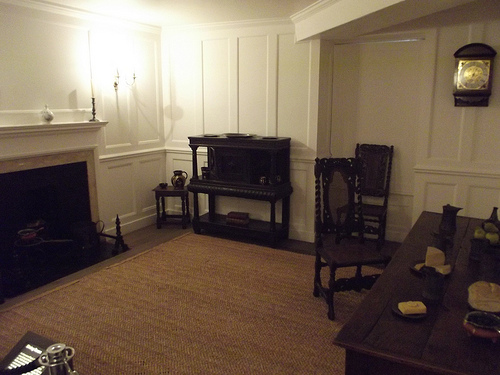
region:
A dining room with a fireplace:
[21, 92, 446, 312]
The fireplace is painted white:
[4, 94, 136, 277]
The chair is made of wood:
[293, 139, 398, 319]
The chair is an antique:
[306, 148, 382, 298]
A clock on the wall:
[442, 26, 493, 111]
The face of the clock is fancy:
[455, 54, 492, 94]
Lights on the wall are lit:
[98, 57, 143, 103]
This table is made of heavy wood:
[334, 284, 481, 369]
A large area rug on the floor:
[140, 225, 250, 349]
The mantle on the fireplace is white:
[4, 115, 107, 145]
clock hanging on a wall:
[448, 35, 498, 122]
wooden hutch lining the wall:
[183, 123, 291, 252]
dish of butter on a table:
[390, 287, 430, 329]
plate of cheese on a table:
[413, 235, 449, 284]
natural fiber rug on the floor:
[134, 270, 208, 340]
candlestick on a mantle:
[80, 72, 101, 124]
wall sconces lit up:
[106, 52, 146, 97]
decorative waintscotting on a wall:
[188, 33, 288, 132]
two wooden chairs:
[304, 144, 397, 328]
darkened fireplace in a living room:
[0, 164, 129, 296]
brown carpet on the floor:
[98, 284, 275, 330]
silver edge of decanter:
[27, 337, 85, 362]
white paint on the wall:
[176, 73, 288, 102]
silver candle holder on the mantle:
[83, 73, 105, 135]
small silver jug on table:
[168, 167, 194, 189]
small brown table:
[143, 175, 198, 228]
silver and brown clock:
[432, 42, 499, 112]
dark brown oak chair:
[303, 150, 389, 295]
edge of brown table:
[331, 306, 381, 352]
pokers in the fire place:
[11, 208, 124, 255]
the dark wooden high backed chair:
[310, 153, 393, 318]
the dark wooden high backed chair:
[352, 138, 394, 242]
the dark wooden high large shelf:
[185, 131, 293, 243]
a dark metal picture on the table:
[172, 168, 187, 186]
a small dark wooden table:
[155, 182, 189, 221]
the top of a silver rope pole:
[41, 343, 73, 371]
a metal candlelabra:
[90, 94, 100, 121]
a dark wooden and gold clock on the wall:
[449, 40, 492, 110]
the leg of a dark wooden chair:
[326, 260, 335, 322]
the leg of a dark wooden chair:
[310, 253, 322, 295]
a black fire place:
[4, 159, 116, 269]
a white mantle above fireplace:
[0, 112, 120, 161]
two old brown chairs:
[283, 145, 400, 322]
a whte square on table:
[382, 278, 439, 326]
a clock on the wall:
[448, 35, 493, 141]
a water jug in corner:
[164, 161, 192, 193]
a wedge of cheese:
[420, 242, 442, 274]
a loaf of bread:
[455, 270, 499, 319]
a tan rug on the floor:
[0, 240, 424, 372]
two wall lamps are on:
[95, 33, 154, 93]